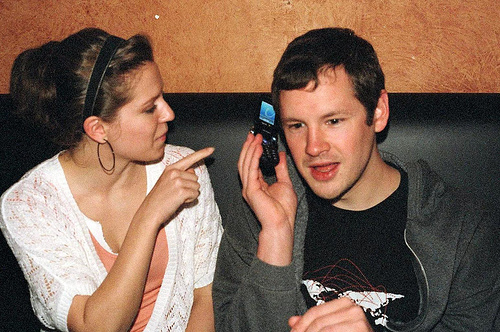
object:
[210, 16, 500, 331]
man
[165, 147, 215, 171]
finger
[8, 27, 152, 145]
hair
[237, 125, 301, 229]
hand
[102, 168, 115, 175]
shadow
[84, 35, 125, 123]
band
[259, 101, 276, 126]
screen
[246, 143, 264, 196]
finger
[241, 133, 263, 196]
finger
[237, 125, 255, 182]
finger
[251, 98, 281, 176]
cellphone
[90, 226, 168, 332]
shirt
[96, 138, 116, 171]
earring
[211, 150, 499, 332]
jacket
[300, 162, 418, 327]
shirt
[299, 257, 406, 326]
design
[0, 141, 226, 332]
cardigan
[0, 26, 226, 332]
woman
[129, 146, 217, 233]
hand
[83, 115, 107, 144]
ear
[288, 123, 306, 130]
eyes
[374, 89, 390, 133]
ear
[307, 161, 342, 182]
mouth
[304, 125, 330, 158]
nose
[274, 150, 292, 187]
thumb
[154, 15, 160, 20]
spot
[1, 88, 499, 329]
couch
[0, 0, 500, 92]
wall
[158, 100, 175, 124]
nose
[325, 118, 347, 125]
eye